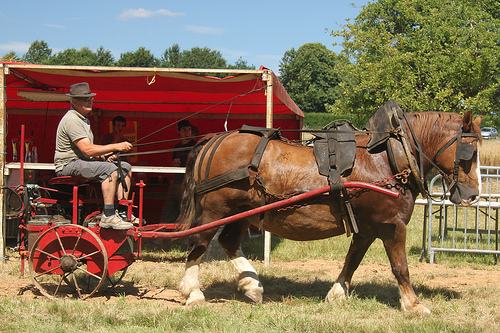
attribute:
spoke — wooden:
[76, 249, 100, 261]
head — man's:
[69, 89, 93, 115]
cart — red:
[23, 173, 140, 303]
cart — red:
[18, 174, 146, 297]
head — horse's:
[438, 110, 483, 207]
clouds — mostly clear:
[112, 5, 228, 36]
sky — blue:
[0, 4, 322, 40]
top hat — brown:
[61, 83, 99, 102]